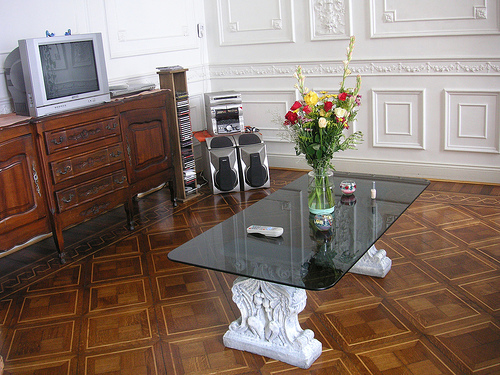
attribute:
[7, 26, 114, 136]
tv — older, small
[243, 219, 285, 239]
remote — gray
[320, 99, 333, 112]
rose — red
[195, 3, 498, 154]
walls — white, textured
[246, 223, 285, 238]
remote control — grey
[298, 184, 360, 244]
candle — small, purple, blue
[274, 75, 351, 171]
flowers — different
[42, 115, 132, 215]
drawers — brown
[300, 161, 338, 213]
glass vase — clear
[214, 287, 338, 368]
stone support — white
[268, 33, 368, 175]
flowers — yellow, red, white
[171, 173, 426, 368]
coffee table — rectangular, glass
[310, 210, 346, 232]
pot — small, blue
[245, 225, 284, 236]
remote — white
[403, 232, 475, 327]
floor — patterned, brown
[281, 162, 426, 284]
glass — black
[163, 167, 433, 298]
glass top — tinted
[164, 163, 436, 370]
table — black, glass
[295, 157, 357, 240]
vase — glass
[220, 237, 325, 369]
leg — intricate, designed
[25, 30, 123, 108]
tv — gray, black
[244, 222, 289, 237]
tv remote — white, grey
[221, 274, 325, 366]
leg — white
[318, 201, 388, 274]
leg — white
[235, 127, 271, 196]
speaker — silver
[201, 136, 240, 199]
speaker — silver